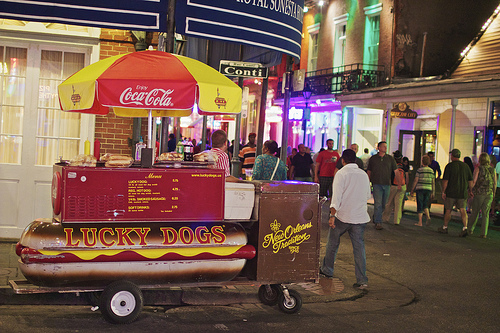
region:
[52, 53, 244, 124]
this is a coca cola umbrella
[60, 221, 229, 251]
this says lucky dogs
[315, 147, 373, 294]
this is a man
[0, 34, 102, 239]
this is a door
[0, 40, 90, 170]
this is a window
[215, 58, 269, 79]
this is a sign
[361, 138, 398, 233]
this is a man walking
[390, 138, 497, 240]
this is some people walking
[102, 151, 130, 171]
these are some buns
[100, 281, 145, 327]
this is a wheel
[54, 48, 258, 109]
red and yellow umbrella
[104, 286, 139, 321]
black wheel of cart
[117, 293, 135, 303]
white hub cap on wheel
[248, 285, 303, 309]
two front wheels of cart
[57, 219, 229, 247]
red writing on side of cart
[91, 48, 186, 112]
red part of umbrella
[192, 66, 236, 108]
yellow part of umbrella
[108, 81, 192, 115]
white writing on umbrella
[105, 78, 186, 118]
logo on side of umbrella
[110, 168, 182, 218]
menu on side o cart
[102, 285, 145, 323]
a black wheel of a cart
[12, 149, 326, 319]
a large hot dog cart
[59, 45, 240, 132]
a red and yellow umbrella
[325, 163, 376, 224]
a man's long sleeve white shirt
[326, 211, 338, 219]
a man's wristwatch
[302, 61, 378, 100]
a black balcony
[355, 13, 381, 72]
a window of a building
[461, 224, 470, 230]
a man's white sock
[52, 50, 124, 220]
the umbrella is red and yellow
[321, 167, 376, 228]
the shirt is white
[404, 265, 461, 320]
the road is black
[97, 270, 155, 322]
the cart has a wheel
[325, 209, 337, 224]
the man is wearing a watch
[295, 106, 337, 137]
the light is purple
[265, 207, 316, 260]
the words are yellow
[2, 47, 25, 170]
the window is glass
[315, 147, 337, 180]
the shirt is red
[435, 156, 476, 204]
the shirt is black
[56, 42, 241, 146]
red adn yellow Coca-Cola umbrella on pole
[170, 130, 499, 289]
people walking on a street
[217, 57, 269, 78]
green and white street sign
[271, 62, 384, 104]
metal bannister around patio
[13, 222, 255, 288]
"Lucky Hot Dogs" advertising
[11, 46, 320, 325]
hot dog stand on wheels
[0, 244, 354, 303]
sidewalk beside street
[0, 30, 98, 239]
glass windows with white frame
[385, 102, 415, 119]
sign outside a store